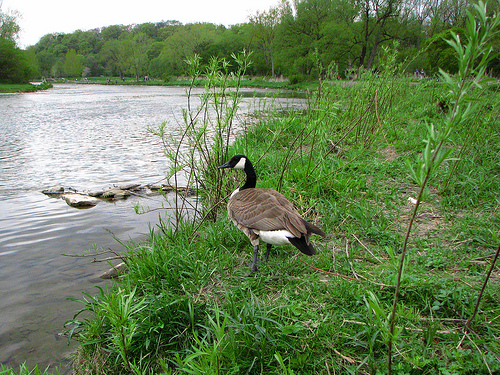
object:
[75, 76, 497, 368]
bank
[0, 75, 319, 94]
river bank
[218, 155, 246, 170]
head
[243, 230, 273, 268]
legs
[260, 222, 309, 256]
feathers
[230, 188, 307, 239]
wing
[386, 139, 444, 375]
stick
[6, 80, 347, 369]
bend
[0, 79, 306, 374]
pond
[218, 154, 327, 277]
goose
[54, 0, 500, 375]
grass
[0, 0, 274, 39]
sky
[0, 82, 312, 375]
water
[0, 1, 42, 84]
green trees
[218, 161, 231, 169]
bill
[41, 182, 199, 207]
rocks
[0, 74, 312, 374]
river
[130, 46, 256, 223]
green plant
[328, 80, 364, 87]
land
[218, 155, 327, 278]
bird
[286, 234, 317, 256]
feathers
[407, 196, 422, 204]
trash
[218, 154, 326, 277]
duck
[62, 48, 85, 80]
tree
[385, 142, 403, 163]
dirt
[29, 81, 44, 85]
canoe